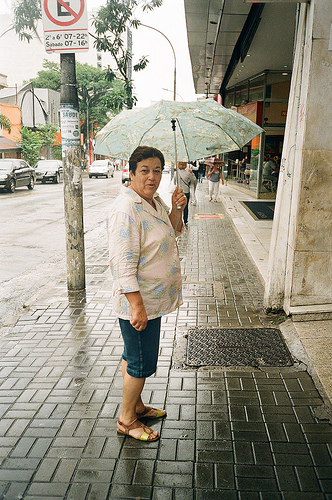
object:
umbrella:
[93, 98, 268, 165]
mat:
[240, 200, 276, 220]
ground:
[0, 157, 332, 498]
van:
[88, 159, 115, 179]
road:
[0, 160, 332, 500]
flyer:
[59, 103, 81, 147]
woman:
[207, 159, 224, 202]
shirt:
[209, 165, 221, 182]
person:
[105, 145, 188, 443]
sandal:
[135, 406, 167, 422]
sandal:
[116, 416, 160, 443]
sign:
[59, 106, 81, 147]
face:
[136, 156, 163, 198]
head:
[128, 145, 166, 201]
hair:
[128, 145, 165, 177]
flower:
[139, 217, 152, 232]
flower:
[155, 236, 169, 261]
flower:
[124, 248, 138, 265]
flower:
[151, 278, 165, 302]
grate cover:
[185, 321, 294, 378]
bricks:
[0, 179, 332, 500]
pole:
[57, 49, 86, 294]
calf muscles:
[121, 357, 145, 409]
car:
[0, 158, 37, 193]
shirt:
[106, 179, 186, 323]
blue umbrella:
[93, 98, 267, 164]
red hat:
[192, 231, 235, 311]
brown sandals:
[116, 399, 168, 443]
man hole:
[186, 325, 295, 370]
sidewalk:
[0, 171, 332, 500]